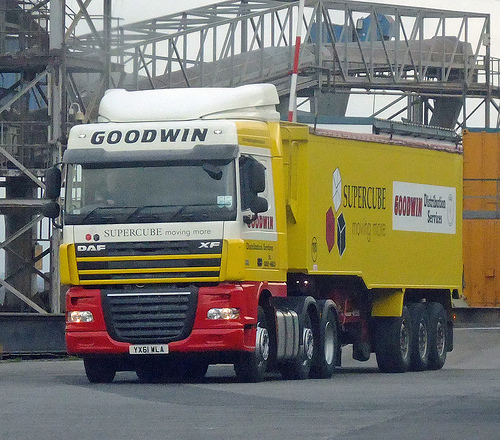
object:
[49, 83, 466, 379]
truck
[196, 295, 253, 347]
part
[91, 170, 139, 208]
man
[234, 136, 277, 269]
door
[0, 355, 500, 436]
street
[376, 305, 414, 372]
wheel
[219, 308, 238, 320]
light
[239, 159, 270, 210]
window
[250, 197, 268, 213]
mirror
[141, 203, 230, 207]
wiper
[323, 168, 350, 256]
logo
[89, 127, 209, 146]
letter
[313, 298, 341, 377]
tire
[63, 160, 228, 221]
windshield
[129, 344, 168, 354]
plate